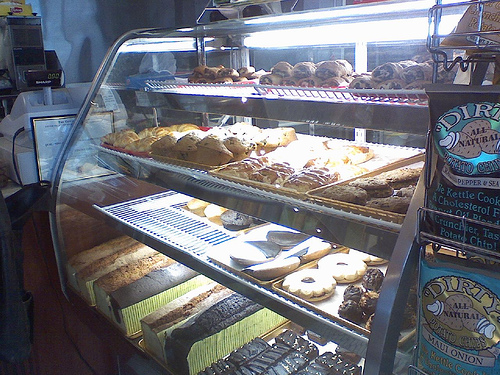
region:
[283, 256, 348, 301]
Doughnuts in a case.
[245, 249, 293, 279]
Long doughnut in a case.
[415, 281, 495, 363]
Bag that says all natural potato chips.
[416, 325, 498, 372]
The chips are Maui Onion.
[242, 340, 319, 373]
Icing on the brownies.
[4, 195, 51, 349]
The stand is wooden.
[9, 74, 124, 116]
Cash register is white.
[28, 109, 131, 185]
Paper in a frame.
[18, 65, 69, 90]
Screen of the register.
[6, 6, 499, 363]
The picture was taken in a bakery.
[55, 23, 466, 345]
case full of baked goods for sale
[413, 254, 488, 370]
bag of chips for sale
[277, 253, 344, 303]
cookies for sale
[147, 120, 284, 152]
tray of muffins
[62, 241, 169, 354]
bakery bread for sale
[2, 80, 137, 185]
cash register for store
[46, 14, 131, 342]
glass container for baked goods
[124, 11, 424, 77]
light on top inside glass case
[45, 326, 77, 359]
floor is reddish in color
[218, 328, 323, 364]
brownies for sale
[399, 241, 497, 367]
bag of chips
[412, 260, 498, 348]
design and log on bag of chips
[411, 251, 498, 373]
bag is light blue and gold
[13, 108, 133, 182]
sign next to the pastry display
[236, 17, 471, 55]
long light in the pastry display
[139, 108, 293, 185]
muffins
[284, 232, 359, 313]
donuts with white glaze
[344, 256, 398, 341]
chocolate pastries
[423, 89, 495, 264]
black bag of chips with light blue writing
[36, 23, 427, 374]
glass pastry display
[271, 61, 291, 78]
a chocolate croissant on a tray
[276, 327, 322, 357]
a brownie with nuts on top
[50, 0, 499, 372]
large glass display case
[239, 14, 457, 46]
light inside display case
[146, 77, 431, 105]
wire shelf inside display case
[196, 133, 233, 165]
muffin on a tray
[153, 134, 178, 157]
muffin inside display case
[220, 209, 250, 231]
a chocolate muffin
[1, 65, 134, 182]
a cash register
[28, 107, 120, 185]
framed certificate leaning on cash register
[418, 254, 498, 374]
Bag of Maui onion flavored chips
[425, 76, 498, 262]
Brown bag of chips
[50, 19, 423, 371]
Bakery display case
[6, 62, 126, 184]
cash register on counter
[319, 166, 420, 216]
cookies on a tray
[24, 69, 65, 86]
price screen on register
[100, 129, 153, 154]
baked croissants on tray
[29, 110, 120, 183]
black and gold picture frame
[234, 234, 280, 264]
chocolate dipped cookie